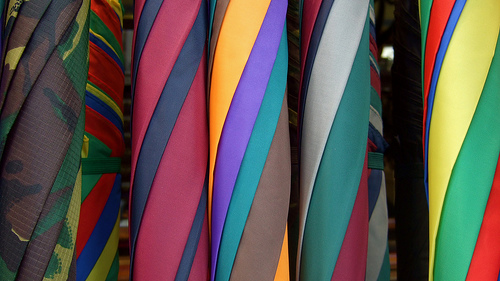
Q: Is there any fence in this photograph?
A: No, there are no fences.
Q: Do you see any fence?
A: No, there are no fences.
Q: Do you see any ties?
A: Yes, there is a tie.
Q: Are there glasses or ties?
A: Yes, there is a tie.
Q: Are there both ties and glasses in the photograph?
A: No, there is a tie but no glasses.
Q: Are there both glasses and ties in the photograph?
A: No, there is a tie but no glasses.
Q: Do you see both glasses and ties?
A: No, there is a tie but no glasses.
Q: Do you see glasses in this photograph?
A: No, there are no glasses.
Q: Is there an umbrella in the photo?
A: Yes, there are umbrellas.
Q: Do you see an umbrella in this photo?
A: Yes, there are umbrellas.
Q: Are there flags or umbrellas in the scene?
A: Yes, there are umbrellas.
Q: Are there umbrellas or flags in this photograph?
A: Yes, there are umbrellas.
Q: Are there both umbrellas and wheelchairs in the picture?
A: No, there are umbrellas but no wheelchairs.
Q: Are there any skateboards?
A: No, there are no skateboards.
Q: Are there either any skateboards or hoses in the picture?
A: No, there are no skateboards or hoses.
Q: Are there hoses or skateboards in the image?
A: No, there are no skateboards or hoses.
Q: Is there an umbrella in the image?
A: Yes, there is an umbrella.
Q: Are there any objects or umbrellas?
A: Yes, there is an umbrella.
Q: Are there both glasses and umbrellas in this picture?
A: No, there is an umbrella but no glasses.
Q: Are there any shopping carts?
A: No, there are no shopping carts.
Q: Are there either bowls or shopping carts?
A: No, there are no shopping carts or bowls.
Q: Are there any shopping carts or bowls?
A: No, there are no shopping carts or bowls.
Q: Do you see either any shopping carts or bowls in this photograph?
A: No, there are no shopping carts or bowls.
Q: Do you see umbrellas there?
A: Yes, there is an umbrella.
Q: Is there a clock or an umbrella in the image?
A: Yes, there is an umbrella.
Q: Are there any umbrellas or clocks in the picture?
A: Yes, there is an umbrella.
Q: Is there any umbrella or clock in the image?
A: Yes, there is an umbrella.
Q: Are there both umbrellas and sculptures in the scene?
A: No, there is an umbrella but no sculptures.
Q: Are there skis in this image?
A: No, there are no skis.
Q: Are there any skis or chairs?
A: No, there are no skis or chairs.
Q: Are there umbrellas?
A: Yes, there is an umbrella.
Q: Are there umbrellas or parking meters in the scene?
A: Yes, there is an umbrella.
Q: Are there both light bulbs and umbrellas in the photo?
A: No, there is an umbrella but no light bulbs.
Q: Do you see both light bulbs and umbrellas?
A: No, there is an umbrella but no light bulbs.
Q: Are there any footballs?
A: No, there are no footballs.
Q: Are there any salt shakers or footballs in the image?
A: No, there are no footballs or salt shakers.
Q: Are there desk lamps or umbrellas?
A: Yes, there is an umbrella.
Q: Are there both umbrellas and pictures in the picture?
A: No, there is an umbrella but no pictures.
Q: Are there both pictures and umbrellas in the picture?
A: No, there is an umbrella but no pictures.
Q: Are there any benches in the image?
A: No, there are no benches.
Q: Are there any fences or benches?
A: No, there are no benches or fences.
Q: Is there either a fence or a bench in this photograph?
A: No, there are no benches or fences.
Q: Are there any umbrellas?
A: Yes, there is an umbrella.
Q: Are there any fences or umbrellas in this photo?
A: Yes, there is an umbrella.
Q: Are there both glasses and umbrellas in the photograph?
A: No, there is an umbrella but no glasses.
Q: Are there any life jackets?
A: No, there are no life jackets.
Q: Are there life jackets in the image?
A: No, there are no life jackets.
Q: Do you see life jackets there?
A: No, there are no life jackets.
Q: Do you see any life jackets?
A: No, there are no life jackets.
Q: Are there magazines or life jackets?
A: No, there are no life jackets or magazines.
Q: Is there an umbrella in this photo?
A: Yes, there is an umbrella.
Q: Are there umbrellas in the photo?
A: Yes, there is an umbrella.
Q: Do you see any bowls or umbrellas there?
A: Yes, there is an umbrella.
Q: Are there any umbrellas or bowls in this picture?
A: Yes, there is an umbrella.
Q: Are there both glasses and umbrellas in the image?
A: No, there is an umbrella but no glasses.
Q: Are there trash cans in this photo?
A: No, there are no trash cans.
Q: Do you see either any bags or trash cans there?
A: No, there are no trash cans or bags.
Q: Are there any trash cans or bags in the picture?
A: No, there are no trash cans or bags.